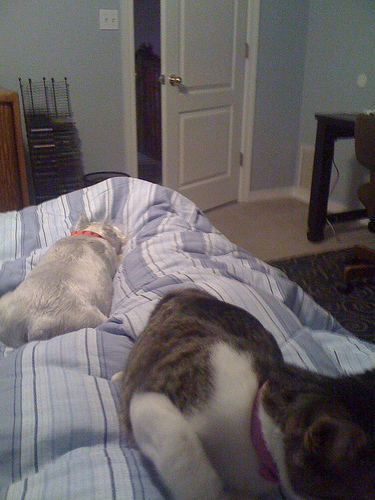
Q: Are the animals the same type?
A: Yes, all the animals are cats.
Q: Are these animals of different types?
A: No, all the animals are cats.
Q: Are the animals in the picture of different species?
A: No, all the animals are cats.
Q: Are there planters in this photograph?
A: No, there are no planters.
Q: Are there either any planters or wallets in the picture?
A: No, there are no planters or wallets.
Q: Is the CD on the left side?
A: Yes, the CD is on the left of the image.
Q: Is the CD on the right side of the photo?
A: No, the CD is on the left of the image.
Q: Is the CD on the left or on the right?
A: The CD is on the left of the image.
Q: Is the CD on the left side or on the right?
A: The CD is on the left of the image.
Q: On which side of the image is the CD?
A: The CD is on the left of the image.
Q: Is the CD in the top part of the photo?
A: Yes, the CD is in the top of the image.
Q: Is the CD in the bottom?
A: No, the CD is in the top of the image.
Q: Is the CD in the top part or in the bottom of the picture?
A: The CD is in the top of the image.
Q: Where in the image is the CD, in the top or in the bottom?
A: The CD is in the top of the image.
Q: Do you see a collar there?
A: Yes, there is a collar.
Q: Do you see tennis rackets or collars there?
A: Yes, there is a collar.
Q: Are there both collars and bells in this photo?
A: No, there is a collar but no bells.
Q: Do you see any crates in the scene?
A: No, there are no crates.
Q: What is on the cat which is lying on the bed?
A: The collar is on the cat.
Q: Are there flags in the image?
A: No, there are no flags.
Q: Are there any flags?
A: No, there are no flags.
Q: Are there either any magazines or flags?
A: No, there are no flags or magazines.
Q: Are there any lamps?
A: No, there are no lamps.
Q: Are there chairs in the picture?
A: Yes, there is a chair.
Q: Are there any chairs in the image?
A: Yes, there is a chair.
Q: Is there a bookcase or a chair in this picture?
A: Yes, there is a chair.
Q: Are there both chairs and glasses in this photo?
A: No, there is a chair but no glasses.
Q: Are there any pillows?
A: No, there are no pillows.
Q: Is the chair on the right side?
A: Yes, the chair is on the right of the image.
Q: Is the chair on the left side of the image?
A: No, the chair is on the right of the image.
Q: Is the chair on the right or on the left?
A: The chair is on the right of the image.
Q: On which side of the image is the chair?
A: The chair is on the right of the image.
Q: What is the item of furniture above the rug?
A: The piece of furniture is a chair.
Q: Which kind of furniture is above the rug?
A: The piece of furniture is a chair.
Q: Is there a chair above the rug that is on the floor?
A: Yes, there is a chair above the rug.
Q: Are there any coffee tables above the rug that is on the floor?
A: No, there is a chair above the rug.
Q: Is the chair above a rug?
A: Yes, the chair is above a rug.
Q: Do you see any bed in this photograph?
A: Yes, there is a bed.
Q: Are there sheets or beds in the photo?
A: Yes, there is a bed.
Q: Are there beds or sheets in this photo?
A: Yes, there is a bed.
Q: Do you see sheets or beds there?
A: Yes, there is a bed.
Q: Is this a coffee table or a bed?
A: This is a bed.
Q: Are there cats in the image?
A: Yes, there is a cat.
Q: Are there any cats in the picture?
A: Yes, there is a cat.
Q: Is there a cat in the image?
A: Yes, there is a cat.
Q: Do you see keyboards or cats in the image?
A: Yes, there is a cat.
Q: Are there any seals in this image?
A: No, there are no seals.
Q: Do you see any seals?
A: No, there are no seals.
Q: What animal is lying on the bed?
A: The cat is lying on the bed.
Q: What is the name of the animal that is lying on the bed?
A: The animal is a cat.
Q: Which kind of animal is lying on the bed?
A: The animal is a cat.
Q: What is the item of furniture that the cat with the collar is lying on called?
A: The piece of furniture is a bed.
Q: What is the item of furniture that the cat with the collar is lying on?
A: The piece of furniture is a bed.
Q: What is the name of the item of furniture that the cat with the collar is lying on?
A: The piece of furniture is a bed.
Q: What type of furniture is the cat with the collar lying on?
A: The cat is lying on the bed.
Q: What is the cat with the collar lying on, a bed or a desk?
A: The cat is lying on a bed.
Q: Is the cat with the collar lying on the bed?
A: Yes, the cat is lying on the bed.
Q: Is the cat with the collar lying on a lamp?
A: No, the cat is lying on the bed.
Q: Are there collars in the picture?
A: Yes, there is a collar.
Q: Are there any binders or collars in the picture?
A: Yes, there is a collar.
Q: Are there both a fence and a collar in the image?
A: No, there is a collar but no fences.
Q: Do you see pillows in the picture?
A: No, there are no pillows.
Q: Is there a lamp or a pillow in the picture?
A: No, there are no pillows or lamps.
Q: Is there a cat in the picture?
A: Yes, there is a cat.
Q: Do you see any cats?
A: Yes, there is a cat.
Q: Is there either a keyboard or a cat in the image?
A: Yes, there is a cat.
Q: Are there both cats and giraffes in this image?
A: No, there is a cat but no giraffes.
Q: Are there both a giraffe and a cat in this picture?
A: No, there is a cat but no giraffes.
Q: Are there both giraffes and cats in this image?
A: No, there is a cat but no giraffes.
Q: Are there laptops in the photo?
A: No, there are no laptops.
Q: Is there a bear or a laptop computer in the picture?
A: No, there are no laptops or bears.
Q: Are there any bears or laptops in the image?
A: No, there are no laptops or bears.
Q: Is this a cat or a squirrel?
A: This is a cat.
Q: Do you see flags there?
A: No, there are no flags.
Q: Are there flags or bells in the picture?
A: No, there are no flags or bells.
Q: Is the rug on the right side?
A: Yes, the rug is on the right of the image.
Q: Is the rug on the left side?
A: No, the rug is on the right of the image.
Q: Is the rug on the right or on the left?
A: The rug is on the right of the image.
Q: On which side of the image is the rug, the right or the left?
A: The rug is on the right of the image.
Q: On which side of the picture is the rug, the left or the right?
A: The rug is on the right of the image.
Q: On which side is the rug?
A: The rug is on the right of the image.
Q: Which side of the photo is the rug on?
A: The rug is on the right of the image.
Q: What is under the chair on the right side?
A: The rug is under the chair.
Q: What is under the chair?
A: The rug is under the chair.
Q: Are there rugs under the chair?
A: Yes, there is a rug under the chair.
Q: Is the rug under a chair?
A: Yes, the rug is under a chair.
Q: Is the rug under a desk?
A: No, the rug is under a chair.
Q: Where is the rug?
A: The rug is on the floor.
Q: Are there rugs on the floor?
A: Yes, there is a rug on the floor.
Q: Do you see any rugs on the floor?
A: Yes, there is a rug on the floor.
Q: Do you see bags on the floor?
A: No, there is a rug on the floor.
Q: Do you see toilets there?
A: No, there are no toilets.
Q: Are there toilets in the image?
A: No, there are no toilets.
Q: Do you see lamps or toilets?
A: No, there are no toilets or lamps.